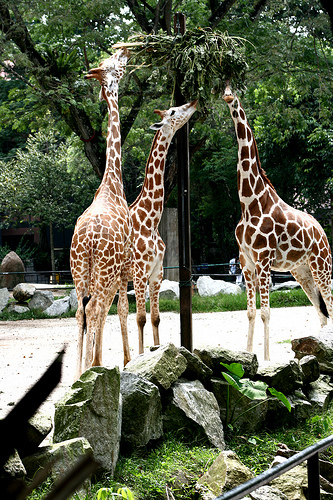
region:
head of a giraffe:
[82, 48, 139, 92]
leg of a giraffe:
[146, 265, 177, 348]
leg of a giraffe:
[132, 292, 152, 347]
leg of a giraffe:
[116, 288, 132, 363]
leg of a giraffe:
[92, 290, 110, 366]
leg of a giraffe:
[66, 279, 92, 361]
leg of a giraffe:
[236, 271, 255, 352]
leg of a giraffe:
[253, 268, 282, 350]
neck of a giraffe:
[220, 121, 287, 173]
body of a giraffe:
[55, 206, 169, 283]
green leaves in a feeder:
[125, 26, 249, 107]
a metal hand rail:
[212, 434, 332, 498]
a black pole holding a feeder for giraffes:
[169, 9, 199, 352]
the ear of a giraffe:
[147, 120, 166, 130]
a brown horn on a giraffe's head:
[151, 106, 164, 115]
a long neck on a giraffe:
[229, 104, 273, 203]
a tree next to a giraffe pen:
[0, 126, 98, 282]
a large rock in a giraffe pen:
[195, 274, 245, 296]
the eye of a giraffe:
[168, 108, 175, 117]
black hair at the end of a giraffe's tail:
[79, 291, 94, 332]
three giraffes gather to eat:
[68, 48, 332, 369]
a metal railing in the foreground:
[217, 435, 329, 499]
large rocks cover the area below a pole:
[26, 334, 332, 499]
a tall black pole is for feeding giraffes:
[171, 12, 192, 350]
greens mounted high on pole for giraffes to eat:
[113, 31, 243, 96]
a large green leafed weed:
[220, 357, 295, 442]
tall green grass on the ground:
[86, 291, 321, 316]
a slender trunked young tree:
[2, 115, 95, 282]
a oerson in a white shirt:
[227, 252, 236, 279]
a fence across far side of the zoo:
[1, 264, 309, 291]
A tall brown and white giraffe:
[212, 75, 331, 343]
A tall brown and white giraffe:
[74, 55, 138, 382]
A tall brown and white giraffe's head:
[217, 73, 246, 126]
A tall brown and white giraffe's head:
[142, 102, 200, 136]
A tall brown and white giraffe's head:
[74, 30, 145, 108]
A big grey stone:
[63, 361, 127, 475]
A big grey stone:
[123, 369, 168, 447]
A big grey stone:
[198, 330, 260, 374]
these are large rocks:
[1, 336, 331, 499]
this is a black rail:
[205, 437, 332, 499]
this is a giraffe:
[68, 45, 134, 388]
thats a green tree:
[0, 131, 101, 287]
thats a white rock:
[197, 274, 241, 295]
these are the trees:
[4, 3, 325, 285]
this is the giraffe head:
[148, 97, 206, 129]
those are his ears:
[147, 106, 165, 129]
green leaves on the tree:
[285, 106, 304, 147]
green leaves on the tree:
[207, 214, 231, 245]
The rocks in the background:
[0, 274, 299, 314]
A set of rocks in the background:
[0, 280, 304, 302]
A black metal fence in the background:
[4, 263, 306, 284]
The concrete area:
[8, 309, 327, 372]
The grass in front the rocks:
[15, 291, 312, 309]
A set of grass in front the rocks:
[1, 288, 309, 303]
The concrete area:
[6, 303, 332, 378]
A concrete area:
[18, 293, 331, 361]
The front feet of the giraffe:
[235, 271, 298, 359]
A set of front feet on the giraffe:
[229, 275, 277, 352]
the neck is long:
[227, 101, 271, 201]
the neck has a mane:
[241, 122, 271, 192]